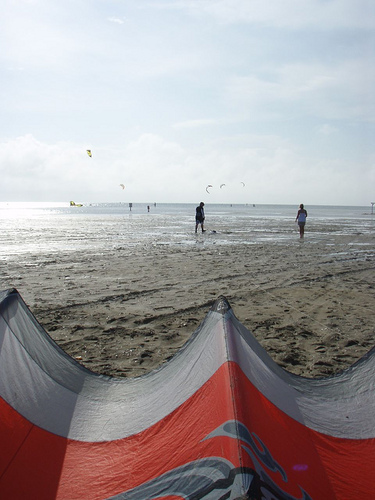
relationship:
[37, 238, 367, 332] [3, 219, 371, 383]
tracks in sand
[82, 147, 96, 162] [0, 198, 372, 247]
kite above water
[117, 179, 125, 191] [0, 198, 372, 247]
kite above water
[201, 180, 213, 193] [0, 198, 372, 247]
kite above water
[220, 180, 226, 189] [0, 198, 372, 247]
kite above water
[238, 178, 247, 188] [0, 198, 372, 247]
kite above water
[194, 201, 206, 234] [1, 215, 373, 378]
man on beach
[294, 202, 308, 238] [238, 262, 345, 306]
people on sand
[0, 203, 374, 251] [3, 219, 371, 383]
water on sand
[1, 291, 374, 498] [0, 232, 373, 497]
sail on beach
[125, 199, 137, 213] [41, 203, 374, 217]
sign on water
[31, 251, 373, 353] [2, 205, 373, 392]
tire tracks on beach sand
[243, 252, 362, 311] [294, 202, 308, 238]
feet prints on people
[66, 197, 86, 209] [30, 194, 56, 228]
kite on water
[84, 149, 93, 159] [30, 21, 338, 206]
kite in sky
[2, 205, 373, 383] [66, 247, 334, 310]
beach sand on beach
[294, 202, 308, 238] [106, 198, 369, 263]
people standing on beach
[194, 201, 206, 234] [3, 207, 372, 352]
man walking along beach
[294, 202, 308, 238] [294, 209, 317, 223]
people wearing a shirt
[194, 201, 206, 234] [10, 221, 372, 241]
man standing on beach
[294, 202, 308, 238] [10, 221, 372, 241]
people standing on beach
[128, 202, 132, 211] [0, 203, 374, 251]
sign in water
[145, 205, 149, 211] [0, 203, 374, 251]
sign in water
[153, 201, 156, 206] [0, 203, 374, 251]
sign in water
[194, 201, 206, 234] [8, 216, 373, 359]
man walking at beach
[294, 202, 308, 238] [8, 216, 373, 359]
people walking at beach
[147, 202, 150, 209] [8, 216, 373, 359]
person walking at beach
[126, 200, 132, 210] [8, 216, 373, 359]
person walking at beach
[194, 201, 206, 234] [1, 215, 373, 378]
man walking on a beach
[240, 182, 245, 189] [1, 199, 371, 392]
kite standing on a beach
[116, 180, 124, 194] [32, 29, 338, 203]
parasail in air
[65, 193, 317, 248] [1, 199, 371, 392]
people walking on a beach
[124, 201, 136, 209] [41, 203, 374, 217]
sign in water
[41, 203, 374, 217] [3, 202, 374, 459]
water on beach